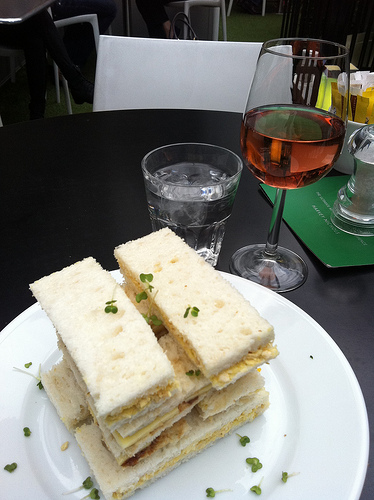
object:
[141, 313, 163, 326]
leaf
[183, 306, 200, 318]
leaf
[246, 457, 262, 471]
leaf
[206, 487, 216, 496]
leaf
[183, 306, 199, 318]
garnish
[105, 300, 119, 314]
garnish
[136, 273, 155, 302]
garnish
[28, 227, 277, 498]
sandwich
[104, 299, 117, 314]
leaf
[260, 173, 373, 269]
green menu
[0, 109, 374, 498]
table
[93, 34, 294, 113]
chair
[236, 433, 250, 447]
leaves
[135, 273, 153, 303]
leaf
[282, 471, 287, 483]
plant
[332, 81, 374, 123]
condiments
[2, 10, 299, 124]
ground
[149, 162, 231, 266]
ice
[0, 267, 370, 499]
white plate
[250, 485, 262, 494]
green plant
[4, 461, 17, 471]
green plant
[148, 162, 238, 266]
water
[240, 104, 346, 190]
drink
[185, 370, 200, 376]
leaves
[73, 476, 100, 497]
plant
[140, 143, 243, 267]
glass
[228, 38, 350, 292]
glass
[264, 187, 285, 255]
stem